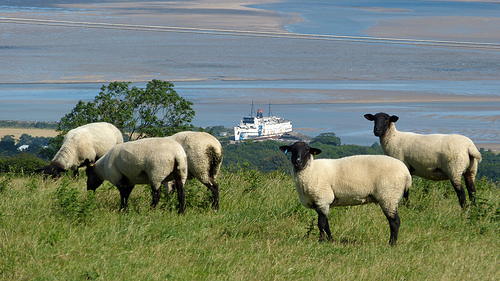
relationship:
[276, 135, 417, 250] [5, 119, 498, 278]
sheep in field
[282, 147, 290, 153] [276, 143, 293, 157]
tag on ear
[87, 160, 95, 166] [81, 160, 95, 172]
spot on ear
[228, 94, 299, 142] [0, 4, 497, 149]
ship in water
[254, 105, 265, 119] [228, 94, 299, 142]
chimney of ship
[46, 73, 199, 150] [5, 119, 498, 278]
tree on field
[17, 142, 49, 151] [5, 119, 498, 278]
roof see in field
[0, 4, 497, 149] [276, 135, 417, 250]
water behind sheep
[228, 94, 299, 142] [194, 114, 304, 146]
ship on port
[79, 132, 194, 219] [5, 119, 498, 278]
sheep in field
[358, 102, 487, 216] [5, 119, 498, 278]
sheep in field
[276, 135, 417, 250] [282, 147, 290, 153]
sheep has tag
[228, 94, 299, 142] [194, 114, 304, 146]
ship docked at port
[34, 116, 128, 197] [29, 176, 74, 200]
sheep eating grass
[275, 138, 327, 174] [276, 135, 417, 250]
head of sheep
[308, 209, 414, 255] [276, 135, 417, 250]
legs of sheep